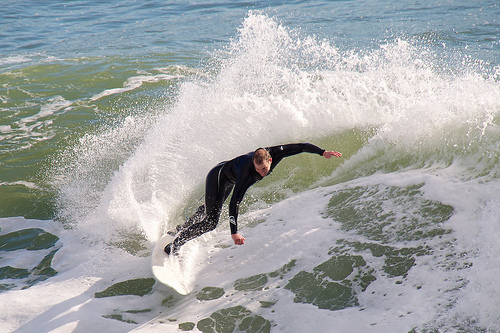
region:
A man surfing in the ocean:
[169, 101, 379, 293]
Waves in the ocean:
[338, 23, 498, 250]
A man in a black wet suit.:
[232, 147, 343, 219]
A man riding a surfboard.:
[149, 165, 264, 330]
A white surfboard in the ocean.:
[150, 213, 193, 330]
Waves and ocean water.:
[32, 27, 212, 177]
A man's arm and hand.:
[275, 121, 354, 169]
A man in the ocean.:
[243, 142, 296, 199]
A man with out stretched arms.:
[220, 107, 377, 251]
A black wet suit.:
[196, 142, 273, 266]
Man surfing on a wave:
[144, 134, 354, 266]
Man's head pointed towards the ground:
[247, 142, 274, 179]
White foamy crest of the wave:
[102, 58, 481, 163]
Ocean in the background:
[4, 4, 498, 73]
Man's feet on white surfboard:
[146, 207, 201, 297]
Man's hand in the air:
[312, 140, 349, 170]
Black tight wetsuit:
[164, 140, 241, 269]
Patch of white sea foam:
[15, 282, 116, 331]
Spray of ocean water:
[233, 7, 488, 102]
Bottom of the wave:
[40, 260, 478, 330]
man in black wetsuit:
[165, 138, 345, 249]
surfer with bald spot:
[252, 147, 277, 181]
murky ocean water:
[27, 54, 134, 129]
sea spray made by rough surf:
[223, 14, 398, 131]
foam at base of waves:
[356, 263, 439, 328]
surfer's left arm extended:
[276, 140, 348, 162]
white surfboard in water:
[150, 224, 207, 294]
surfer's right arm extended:
[227, 177, 246, 246]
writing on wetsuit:
[225, 213, 236, 225]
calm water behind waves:
[49, 3, 174, 60]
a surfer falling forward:
[151, 142, 338, 259]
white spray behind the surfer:
[111, 62, 376, 136]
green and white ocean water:
[275, 202, 436, 322]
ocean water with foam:
[2, 227, 117, 314]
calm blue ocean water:
[21, 2, 96, 40]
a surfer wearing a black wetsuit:
[188, 148, 338, 233]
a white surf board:
[141, 224, 195, 307]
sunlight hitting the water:
[437, 7, 490, 104]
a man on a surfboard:
[140, 132, 292, 297]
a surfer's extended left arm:
[296, 135, 338, 164]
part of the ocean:
[441, 137, 446, 161]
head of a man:
[250, 154, 285, 179]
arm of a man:
[238, 200, 240, 225]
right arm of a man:
[233, 200, 238, 230]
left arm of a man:
[280, 145, 303, 162]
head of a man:
[259, 152, 266, 162]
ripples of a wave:
[418, 157, 446, 244]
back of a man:
[213, 173, 220, 185]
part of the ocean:
[166, 120, 183, 137]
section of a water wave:
[373, 82, 422, 131]